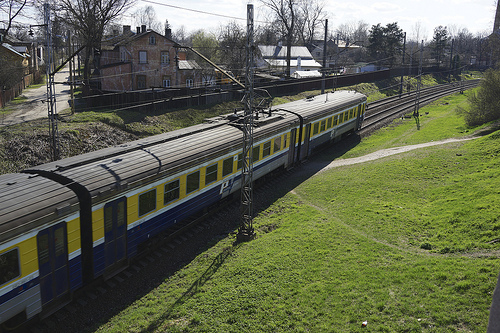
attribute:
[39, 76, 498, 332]
meadow — green, grassy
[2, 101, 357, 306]
stripe — blue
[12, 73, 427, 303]
train — blue, yellow, white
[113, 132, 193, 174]
roof — gray, top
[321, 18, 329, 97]
pole — metal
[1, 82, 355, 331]
train — passenger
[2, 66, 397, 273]
train — yellow, white, blue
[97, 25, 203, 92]
house — side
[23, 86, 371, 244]
train — yellow, blue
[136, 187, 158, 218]
window — closed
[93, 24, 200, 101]
house — pretty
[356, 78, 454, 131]
tracks — sets, train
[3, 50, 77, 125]
road — gray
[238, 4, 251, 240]
pole — metal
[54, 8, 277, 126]
house — pink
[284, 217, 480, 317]
grass — short, green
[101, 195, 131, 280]
door — side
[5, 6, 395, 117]
city — small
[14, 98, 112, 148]
slope — rocky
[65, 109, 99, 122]
grass — patchy